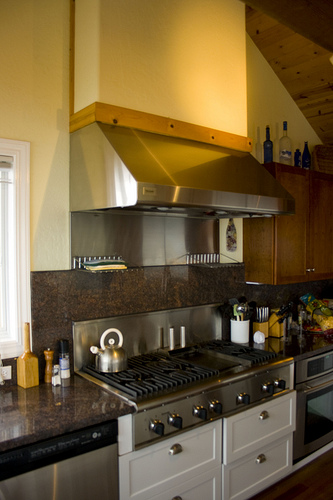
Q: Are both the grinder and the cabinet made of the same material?
A: Yes, both the grinder and the cabinet are made of wood.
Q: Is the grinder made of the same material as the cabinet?
A: Yes, both the grinder and the cabinet are made of wood.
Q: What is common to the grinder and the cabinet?
A: The material, both the grinder and the cabinet are wooden.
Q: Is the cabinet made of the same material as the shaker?
A: Yes, both the cabinet and the shaker are made of wood.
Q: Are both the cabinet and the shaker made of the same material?
A: Yes, both the cabinet and the shaker are made of wood.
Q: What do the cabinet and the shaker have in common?
A: The material, both the cabinet and the shaker are wooden.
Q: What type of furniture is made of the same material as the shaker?
A: The cabinet is made of the same material as the shaker.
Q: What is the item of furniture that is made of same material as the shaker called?
A: The piece of furniture is a cabinet.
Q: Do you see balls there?
A: No, there are no balls.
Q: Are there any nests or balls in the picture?
A: No, there are no balls or nests.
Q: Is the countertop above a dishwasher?
A: Yes, the countertop is above a dishwasher.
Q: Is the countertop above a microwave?
A: No, the countertop is above a dishwasher.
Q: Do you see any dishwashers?
A: Yes, there is a dishwasher.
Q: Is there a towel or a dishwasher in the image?
A: Yes, there is a dishwasher.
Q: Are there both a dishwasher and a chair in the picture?
A: No, there is a dishwasher but no chairs.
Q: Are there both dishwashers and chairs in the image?
A: No, there is a dishwasher but no chairs.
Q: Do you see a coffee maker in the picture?
A: No, there are no coffee makers.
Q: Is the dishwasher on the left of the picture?
A: Yes, the dishwasher is on the left of the image.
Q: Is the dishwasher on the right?
A: No, the dishwasher is on the left of the image.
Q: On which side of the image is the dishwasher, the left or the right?
A: The dishwasher is on the left of the image.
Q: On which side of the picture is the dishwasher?
A: The dishwasher is on the left of the image.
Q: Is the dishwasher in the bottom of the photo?
A: Yes, the dishwasher is in the bottom of the image.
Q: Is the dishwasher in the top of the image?
A: No, the dishwasher is in the bottom of the image.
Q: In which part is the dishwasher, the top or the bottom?
A: The dishwasher is in the bottom of the image.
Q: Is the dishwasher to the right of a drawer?
A: No, the dishwasher is to the left of a drawer.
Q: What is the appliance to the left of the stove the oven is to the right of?
A: The appliance is a dishwasher.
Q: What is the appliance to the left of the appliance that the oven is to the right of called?
A: The appliance is a dishwasher.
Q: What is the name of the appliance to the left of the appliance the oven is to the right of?
A: The appliance is a dishwasher.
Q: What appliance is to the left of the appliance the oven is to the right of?
A: The appliance is a dishwasher.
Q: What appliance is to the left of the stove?
A: The appliance is a dishwasher.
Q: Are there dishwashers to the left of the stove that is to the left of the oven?
A: Yes, there is a dishwasher to the left of the stove.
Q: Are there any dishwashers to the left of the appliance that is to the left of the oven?
A: Yes, there is a dishwasher to the left of the stove.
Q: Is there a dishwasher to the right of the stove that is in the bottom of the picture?
A: No, the dishwasher is to the left of the stove.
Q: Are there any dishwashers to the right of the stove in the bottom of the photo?
A: No, the dishwasher is to the left of the stove.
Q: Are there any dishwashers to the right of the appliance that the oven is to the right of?
A: No, the dishwasher is to the left of the stove.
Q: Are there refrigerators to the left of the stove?
A: No, there is a dishwasher to the left of the stove.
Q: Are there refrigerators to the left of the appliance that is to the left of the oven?
A: No, there is a dishwasher to the left of the stove.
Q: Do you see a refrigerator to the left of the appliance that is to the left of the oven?
A: No, there is a dishwasher to the left of the stove.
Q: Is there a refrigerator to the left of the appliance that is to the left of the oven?
A: No, there is a dishwasher to the left of the stove.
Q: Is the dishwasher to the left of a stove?
A: Yes, the dishwasher is to the left of a stove.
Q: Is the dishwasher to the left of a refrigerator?
A: No, the dishwasher is to the left of a stove.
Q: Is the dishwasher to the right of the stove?
A: No, the dishwasher is to the left of the stove.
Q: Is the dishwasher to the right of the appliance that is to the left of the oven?
A: No, the dishwasher is to the left of the stove.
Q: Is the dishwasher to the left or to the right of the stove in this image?
A: The dishwasher is to the left of the stove.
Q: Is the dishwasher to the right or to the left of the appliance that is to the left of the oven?
A: The dishwasher is to the left of the stove.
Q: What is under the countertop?
A: The dishwasher is under the countertop.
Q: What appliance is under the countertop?
A: The appliance is a dishwasher.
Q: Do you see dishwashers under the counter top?
A: Yes, there is a dishwasher under the counter top.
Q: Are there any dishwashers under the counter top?
A: Yes, there is a dishwasher under the counter top.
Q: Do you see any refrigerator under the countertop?
A: No, there is a dishwasher under the countertop.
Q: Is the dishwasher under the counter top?
A: Yes, the dishwasher is under the counter top.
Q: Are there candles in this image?
A: No, there are no candles.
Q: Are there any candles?
A: No, there are no candles.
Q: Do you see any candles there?
A: No, there are no candles.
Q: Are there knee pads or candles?
A: No, there are no candles or knee pads.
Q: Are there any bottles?
A: Yes, there is a bottle.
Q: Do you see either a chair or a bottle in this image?
A: Yes, there is a bottle.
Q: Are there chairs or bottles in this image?
A: Yes, there is a bottle.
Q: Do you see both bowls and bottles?
A: No, there is a bottle but no bowls.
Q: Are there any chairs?
A: No, there are no chairs.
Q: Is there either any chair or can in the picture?
A: No, there are no chairs or cans.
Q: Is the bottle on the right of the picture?
A: Yes, the bottle is on the right of the image.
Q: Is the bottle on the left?
A: No, the bottle is on the right of the image.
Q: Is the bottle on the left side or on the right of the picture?
A: The bottle is on the right of the image.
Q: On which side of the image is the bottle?
A: The bottle is on the right of the image.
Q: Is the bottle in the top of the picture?
A: Yes, the bottle is in the top of the image.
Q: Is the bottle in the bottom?
A: No, the bottle is in the top of the image.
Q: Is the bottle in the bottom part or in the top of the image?
A: The bottle is in the top of the image.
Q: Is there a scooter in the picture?
A: No, there are no scooters.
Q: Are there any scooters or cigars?
A: No, there are no scooters or cigars.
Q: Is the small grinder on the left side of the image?
A: Yes, the grinder is on the left of the image.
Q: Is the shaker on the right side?
A: No, the shaker is on the left of the image.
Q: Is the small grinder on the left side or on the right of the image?
A: The shaker is on the left of the image.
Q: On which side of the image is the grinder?
A: The grinder is on the left of the image.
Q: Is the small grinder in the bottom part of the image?
A: Yes, the grinder is in the bottom of the image.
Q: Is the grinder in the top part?
A: No, the grinder is in the bottom of the image.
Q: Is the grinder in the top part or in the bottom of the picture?
A: The grinder is in the bottom of the image.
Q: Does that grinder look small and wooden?
A: Yes, the grinder is small and wooden.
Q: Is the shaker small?
A: Yes, the shaker is small.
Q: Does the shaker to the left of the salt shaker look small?
A: Yes, the shaker is small.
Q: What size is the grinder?
A: The grinder is small.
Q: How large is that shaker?
A: The shaker is small.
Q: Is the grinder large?
A: No, the grinder is small.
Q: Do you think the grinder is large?
A: No, the grinder is small.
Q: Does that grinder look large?
A: No, the grinder is small.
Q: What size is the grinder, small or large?
A: The grinder is small.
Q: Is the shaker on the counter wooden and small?
A: Yes, the grinder is wooden and small.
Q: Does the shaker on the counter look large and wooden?
A: No, the grinder is wooden but small.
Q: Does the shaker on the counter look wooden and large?
A: No, the grinder is wooden but small.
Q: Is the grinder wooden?
A: Yes, the grinder is wooden.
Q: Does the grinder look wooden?
A: Yes, the grinder is wooden.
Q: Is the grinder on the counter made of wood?
A: Yes, the grinder is made of wood.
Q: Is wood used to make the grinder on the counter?
A: Yes, the grinder is made of wood.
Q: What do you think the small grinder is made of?
A: The grinder is made of wood.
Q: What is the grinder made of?
A: The grinder is made of wood.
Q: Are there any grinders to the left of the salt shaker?
A: Yes, there is a grinder to the left of the salt shaker.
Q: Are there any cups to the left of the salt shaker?
A: No, there is a grinder to the left of the salt shaker.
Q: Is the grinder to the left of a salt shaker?
A: Yes, the grinder is to the left of a salt shaker.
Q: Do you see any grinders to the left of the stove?
A: Yes, there is a grinder to the left of the stove.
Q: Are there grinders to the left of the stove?
A: Yes, there is a grinder to the left of the stove.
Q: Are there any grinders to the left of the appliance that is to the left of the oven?
A: Yes, there is a grinder to the left of the stove.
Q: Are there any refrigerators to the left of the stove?
A: No, there is a grinder to the left of the stove.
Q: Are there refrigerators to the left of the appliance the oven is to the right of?
A: No, there is a grinder to the left of the stove.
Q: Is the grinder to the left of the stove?
A: Yes, the grinder is to the left of the stove.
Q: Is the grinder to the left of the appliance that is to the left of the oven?
A: Yes, the grinder is to the left of the stove.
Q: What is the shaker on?
A: The shaker is on the counter.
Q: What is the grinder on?
A: The shaker is on the counter.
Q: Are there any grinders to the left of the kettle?
A: Yes, there is a grinder to the left of the kettle.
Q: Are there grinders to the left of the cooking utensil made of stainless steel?
A: Yes, there is a grinder to the left of the kettle.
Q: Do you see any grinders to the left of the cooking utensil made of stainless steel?
A: Yes, there is a grinder to the left of the kettle.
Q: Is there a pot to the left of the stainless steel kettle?
A: No, there is a grinder to the left of the kettle.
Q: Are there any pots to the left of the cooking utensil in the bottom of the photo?
A: No, there is a grinder to the left of the kettle.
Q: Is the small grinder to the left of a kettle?
A: Yes, the shaker is to the left of a kettle.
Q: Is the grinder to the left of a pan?
A: No, the grinder is to the left of a kettle.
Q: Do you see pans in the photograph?
A: No, there are no pans.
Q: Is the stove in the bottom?
A: Yes, the stove is in the bottom of the image.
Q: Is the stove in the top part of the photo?
A: No, the stove is in the bottom of the image.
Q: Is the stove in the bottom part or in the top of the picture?
A: The stove is in the bottom of the image.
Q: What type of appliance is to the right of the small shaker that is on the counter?
A: The appliance is a stove.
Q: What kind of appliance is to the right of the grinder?
A: The appliance is a stove.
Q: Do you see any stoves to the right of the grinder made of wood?
A: Yes, there is a stove to the right of the shaker.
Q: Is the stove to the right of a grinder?
A: Yes, the stove is to the right of a grinder.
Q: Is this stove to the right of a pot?
A: No, the stove is to the right of a grinder.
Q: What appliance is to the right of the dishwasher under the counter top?
A: The appliance is a stove.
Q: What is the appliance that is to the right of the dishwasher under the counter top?
A: The appliance is a stove.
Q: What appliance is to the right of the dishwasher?
A: The appliance is a stove.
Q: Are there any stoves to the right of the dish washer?
A: Yes, there is a stove to the right of the dish washer.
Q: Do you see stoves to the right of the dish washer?
A: Yes, there is a stove to the right of the dish washer.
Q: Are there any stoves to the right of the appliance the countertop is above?
A: Yes, there is a stove to the right of the dish washer.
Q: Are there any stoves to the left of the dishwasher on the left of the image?
A: No, the stove is to the right of the dishwasher.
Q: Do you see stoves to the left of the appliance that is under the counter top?
A: No, the stove is to the right of the dishwasher.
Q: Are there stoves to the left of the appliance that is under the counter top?
A: No, the stove is to the right of the dishwasher.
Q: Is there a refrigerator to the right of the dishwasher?
A: No, there is a stove to the right of the dishwasher.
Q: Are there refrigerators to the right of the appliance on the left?
A: No, there is a stove to the right of the dishwasher.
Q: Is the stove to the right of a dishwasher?
A: Yes, the stove is to the right of a dishwasher.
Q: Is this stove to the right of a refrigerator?
A: No, the stove is to the right of a dishwasher.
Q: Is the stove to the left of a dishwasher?
A: No, the stove is to the right of a dishwasher.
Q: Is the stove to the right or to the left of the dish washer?
A: The stove is to the right of the dish washer.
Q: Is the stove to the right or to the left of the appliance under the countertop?
A: The stove is to the right of the dish washer.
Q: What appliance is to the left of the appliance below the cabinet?
A: The appliance is a stove.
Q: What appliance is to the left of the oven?
A: The appliance is a stove.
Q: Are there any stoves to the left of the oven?
A: Yes, there is a stove to the left of the oven.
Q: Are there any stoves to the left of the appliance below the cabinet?
A: Yes, there is a stove to the left of the oven.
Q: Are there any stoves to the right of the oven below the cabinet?
A: No, the stove is to the left of the oven.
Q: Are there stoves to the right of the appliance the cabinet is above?
A: No, the stove is to the left of the oven.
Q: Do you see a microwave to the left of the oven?
A: No, there is a stove to the left of the oven.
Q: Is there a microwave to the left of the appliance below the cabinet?
A: No, there is a stove to the left of the oven.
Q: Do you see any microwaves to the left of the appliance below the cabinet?
A: No, there is a stove to the left of the oven.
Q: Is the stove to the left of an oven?
A: Yes, the stove is to the left of an oven.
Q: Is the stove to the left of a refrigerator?
A: No, the stove is to the left of an oven.